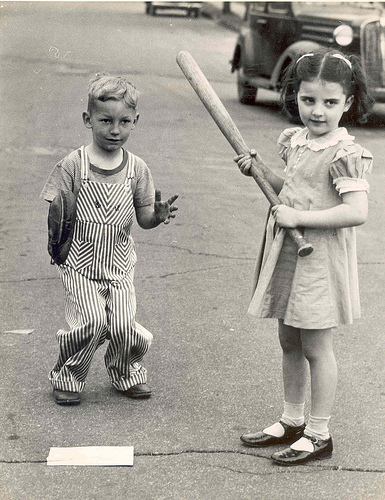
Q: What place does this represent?
A: It represents the street.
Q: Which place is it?
A: It is a street.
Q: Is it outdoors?
A: Yes, it is outdoors.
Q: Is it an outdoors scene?
A: Yes, it is outdoors.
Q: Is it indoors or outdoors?
A: It is outdoors.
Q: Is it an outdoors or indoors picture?
A: It is outdoors.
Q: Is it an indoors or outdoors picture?
A: It is outdoors.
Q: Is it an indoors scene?
A: No, it is outdoors.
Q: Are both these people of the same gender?
A: No, they are both male and female.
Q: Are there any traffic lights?
A: No, there are no traffic lights.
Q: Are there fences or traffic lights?
A: No, there are no traffic lights or fences.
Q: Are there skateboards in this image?
A: No, there are no skateboards.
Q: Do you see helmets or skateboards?
A: No, there are no skateboards or helmets.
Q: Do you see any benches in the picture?
A: No, there are no benches.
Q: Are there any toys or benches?
A: No, there are no benches or toys.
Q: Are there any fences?
A: No, there are no fences.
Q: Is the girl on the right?
A: Yes, the girl is on the right of the image.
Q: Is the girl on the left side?
A: No, the girl is on the right of the image.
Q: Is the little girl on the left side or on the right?
A: The girl is on the right of the image.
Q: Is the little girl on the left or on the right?
A: The girl is on the right of the image.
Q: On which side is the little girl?
A: The girl is on the right of the image.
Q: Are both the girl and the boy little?
A: Yes, both the girl and the boy are little.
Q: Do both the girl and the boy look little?
A: Yes, both the girl and the boy are little.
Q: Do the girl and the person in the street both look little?
A: Yes, both the girl and the boy are little.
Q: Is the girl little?
A: Yes, the girl is little.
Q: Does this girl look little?
A: Yes, the girl is little.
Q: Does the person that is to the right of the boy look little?
A: Yes, the girl is little.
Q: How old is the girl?
A: The girl is little.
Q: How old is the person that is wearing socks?
A: The girl is little.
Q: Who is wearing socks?
A: The girl is wearing socks.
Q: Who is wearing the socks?
A: The girl is wearing socks.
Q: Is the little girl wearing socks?
A: Yes, the girl is wearing socks.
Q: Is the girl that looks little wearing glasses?
A: No, the girl is wearing socks.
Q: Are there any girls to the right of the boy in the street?
A: Yes, there is a girl to the right of the boy.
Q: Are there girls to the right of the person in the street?
A: Yes, there is a girl to the right of the boy.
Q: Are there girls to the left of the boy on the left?
A: No, the girl is to the right of the boy.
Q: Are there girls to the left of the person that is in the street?
A: No, the girl is to the right of the boy.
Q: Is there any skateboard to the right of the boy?
A: No, there is a girl to the right of the boy.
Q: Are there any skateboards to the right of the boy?
A: No, there is a girl to the right of the boy.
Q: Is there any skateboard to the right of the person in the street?
A: No, there is a girl to the right of the boy.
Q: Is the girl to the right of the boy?
A: Yes, the girl is to the right of the boy.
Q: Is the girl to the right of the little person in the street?
A: Yes, the girl is to the right of the boy.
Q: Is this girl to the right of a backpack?
A: No, the girl is to the right of the boy.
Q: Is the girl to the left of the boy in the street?
A: No, the girl is to the right of the boy.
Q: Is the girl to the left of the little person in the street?
A: No, the girl is to the right of the boy.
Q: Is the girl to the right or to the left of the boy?
A: The girl is to the right of the boy.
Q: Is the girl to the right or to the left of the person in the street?
A: The girl is to the right of the boy.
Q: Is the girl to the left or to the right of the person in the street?
A: The girl is to the right of the boy.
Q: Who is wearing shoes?
A: The girl is wearing shoes.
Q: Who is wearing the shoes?
A: The girl is wearing shoes.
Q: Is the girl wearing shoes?
A: Yes, the girl is wearing shoes.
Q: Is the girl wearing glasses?
A: No, the girl is wearing shoes.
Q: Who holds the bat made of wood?
A: The girl holds the bat.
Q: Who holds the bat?
A: The girl holds the bat.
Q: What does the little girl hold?
A: The girl holds the bat.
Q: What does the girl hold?
A: The girl holds the bat.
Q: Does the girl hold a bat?
A: Yes, the girl holds a bat.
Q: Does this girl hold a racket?
A: No, the girl holds a bat.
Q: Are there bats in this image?
A: Yes, there is a bat.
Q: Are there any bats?
A: Yes, there is a bat.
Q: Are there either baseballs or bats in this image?
A: Yes, there is a bat.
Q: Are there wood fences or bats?
A: Yes, there is a wood bat.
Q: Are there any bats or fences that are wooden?
A: Yes, the bat is wooden.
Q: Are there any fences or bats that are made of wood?
A: Yes, the bat is made of wood.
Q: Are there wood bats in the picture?
A: Yes, there is a wood bat.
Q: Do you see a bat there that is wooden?
A: Yes, there is a bat that is wooden.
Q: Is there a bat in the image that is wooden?
A: Yes, there is a bat that is wooden.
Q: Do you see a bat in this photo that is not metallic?
A: Yes, there is a wooden bat.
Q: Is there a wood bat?
A: Yes, there is a bat that is made of wood.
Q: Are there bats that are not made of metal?
A: Yes, there is a bat that is made of wood.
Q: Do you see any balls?
A: No, there are no balls.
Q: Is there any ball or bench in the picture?
A: No, there are no balls or benches.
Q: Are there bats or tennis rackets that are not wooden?
A: No, there is a bat but it is wooden.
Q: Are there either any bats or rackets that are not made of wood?
A: No, there is a bat but it is made of wood.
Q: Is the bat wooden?
A: Yes, the bat is wooden.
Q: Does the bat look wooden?
A: Yes, the bat is wooden.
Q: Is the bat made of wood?
A: Yes, the bat is made of wood.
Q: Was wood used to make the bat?
A: Yes, the bat is made of wood.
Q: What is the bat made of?
A: The bat is made of wood.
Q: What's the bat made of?
A: The bat is made of wood.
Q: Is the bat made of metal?
A: No, the bat is made of wood.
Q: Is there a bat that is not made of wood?
A: No, there is a bat but it is made of wood.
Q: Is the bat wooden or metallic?
A: The bat is wooden.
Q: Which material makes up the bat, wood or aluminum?
A: The bat is made of wood.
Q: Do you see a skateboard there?
A: No, there are no skateboards.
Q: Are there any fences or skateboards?
A: No, there are no skateboards or fences.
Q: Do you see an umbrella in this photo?
A: No, there are no umbrellas.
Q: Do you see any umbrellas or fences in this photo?
A: No, there are no umbrellas or fences.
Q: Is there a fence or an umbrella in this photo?
A: No, there are no umbrellas or fences.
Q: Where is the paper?
A: The paper is on the pavement.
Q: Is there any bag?
A: No, there are no bags.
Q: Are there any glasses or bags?
A: No, there are no bags or glasses.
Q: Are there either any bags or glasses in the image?
A: No, there are no bags or glasses.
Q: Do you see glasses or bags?
A: No, there are no bags or glasses.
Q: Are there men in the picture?
A: No, there are no men.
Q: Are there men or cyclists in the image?
A: No, there are no men or cyclists.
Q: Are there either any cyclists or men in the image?
A: No, there are no men or cyclists.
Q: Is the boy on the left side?
A: Yes, the boy is on the left of the image.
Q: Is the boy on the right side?
A: No, the boy is on the left of the image.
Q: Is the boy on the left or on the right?
A: The boy is on the left of the image.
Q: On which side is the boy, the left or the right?
A: The boy is on the left of the image.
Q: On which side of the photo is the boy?
A: The boy is on the left of the image.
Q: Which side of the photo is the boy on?
A: The boy is on the left of the image.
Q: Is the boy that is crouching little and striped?
A: Yes, the boy is little and striped.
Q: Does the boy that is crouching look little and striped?
A: Yes, the boy is little and striped.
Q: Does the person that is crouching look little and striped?
A: Yes, the boy is little and striped.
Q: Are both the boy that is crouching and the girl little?
A: Yes, both the boy and the girl are little.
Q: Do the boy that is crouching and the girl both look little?
A: Yes, both the boy and the girl are little.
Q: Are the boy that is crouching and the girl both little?
A: Yes, both the boy and the girl are little.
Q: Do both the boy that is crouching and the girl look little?
A: Yes, both the boy and the girl are little.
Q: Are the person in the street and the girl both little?
A: Yes, both the boy and the girl are little.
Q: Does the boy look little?
A: Yes, the boy is little.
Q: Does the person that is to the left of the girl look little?
A: Yes, the boy is little.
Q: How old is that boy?
A: The boy is little.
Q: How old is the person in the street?
A: The boy is little.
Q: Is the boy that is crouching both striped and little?
A: Yes, the boy is striped and little.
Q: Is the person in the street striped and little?
A: Yes, the boy is striped and little.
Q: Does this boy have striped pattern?
A: Yes, the boy is striped.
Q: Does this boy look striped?
A: Yes, the boy is striped.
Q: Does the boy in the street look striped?
A: Yes, the boy is striped.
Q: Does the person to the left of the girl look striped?
A: Yes, the boy is striped.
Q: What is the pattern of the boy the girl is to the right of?
A: The boy is striped.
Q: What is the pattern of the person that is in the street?
A: The boy is striped.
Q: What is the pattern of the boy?
A: The boy is striped.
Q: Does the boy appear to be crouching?
A: Yes, the boy is crouching.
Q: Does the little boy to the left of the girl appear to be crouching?
A: Yes, the boy is crouching.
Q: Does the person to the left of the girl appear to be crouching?
A: Yes, the boy is crouching.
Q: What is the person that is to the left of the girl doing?
A: The boy is crouching.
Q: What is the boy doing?
A: The boy is crouching.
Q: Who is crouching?
A: The boy is crouching.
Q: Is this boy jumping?
A: No, the boy is crouching.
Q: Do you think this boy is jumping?
A: No, the boy is crouching.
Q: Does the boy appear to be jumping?
A: No, the boy is crouching.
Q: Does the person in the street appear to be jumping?
A: No, the boy is crouching.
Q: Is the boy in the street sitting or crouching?
A: The boy is crouching.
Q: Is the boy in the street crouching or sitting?
A: The boy is crouching.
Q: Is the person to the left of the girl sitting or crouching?
A: The boy is crouching.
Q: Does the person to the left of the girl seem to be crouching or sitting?
A: The boy is crouching.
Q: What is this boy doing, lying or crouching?
A: The boy is crouching.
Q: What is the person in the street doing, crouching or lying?
A: The boy is crouching.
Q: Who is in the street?
A: The boy is in the street.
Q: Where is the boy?
A: The boy is in the street.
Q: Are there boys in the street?
A: Yes, there is a boy in the street.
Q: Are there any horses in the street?
A: No, there is a boy in the street.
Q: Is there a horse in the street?
A: No, there is a boy in the street.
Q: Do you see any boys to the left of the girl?
A: Yes, there is a boy to the left of the girl.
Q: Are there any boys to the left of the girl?
A: Yes, there is a boy to the left of the girl.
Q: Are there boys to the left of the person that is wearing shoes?
A: Yes, there is a boy to the left of the girl.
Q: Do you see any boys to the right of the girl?
A: No, the boy is to the left of the girl.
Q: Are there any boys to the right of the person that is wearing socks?
A: No, the boy is to the left of the girl.